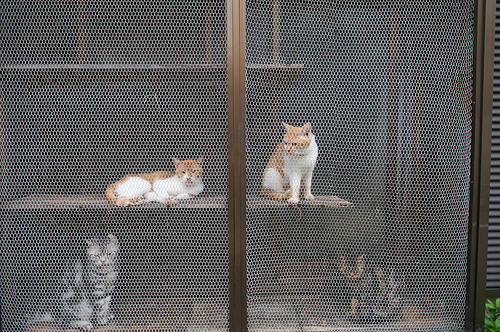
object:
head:
[282, 121, 312, 153]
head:
[338, 252, 365, 278]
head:
[172, 155, 204, 181]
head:
[84, 235, 120, 265]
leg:
[116, 188, 143, 206]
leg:
[287, 175, 302, 203]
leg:
[288, 171, 302, 197]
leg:
[98, 284, 115, 315]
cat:
[104, 156, 205, 207]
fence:
[296, 46, 465, 122]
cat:
[11, 233, 123, 331]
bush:
[482, 299, 499, 332]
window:
[0, 69, 230, 155]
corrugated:
[485, 167, 498, 289]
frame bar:
[226, 57, 248, 332]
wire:
[264, 273, 429, 303]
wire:
[412, 200, 456, 211]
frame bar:
[464, 160, 489, 331]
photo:
[0, 0, 499, 332]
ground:
[255, 324, 350, 331]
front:
[287, 198, 300, 204]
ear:
[302, 122, 312, 131]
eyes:
[292, 143, 297, 146]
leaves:
[485, 318, 495, 332]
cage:
[0, 0, 500, 331]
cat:
[260, 121, 319, 205]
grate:
[60, 116, 105, 135]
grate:
[15, 50, 103, 82]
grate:
[2, 210, 59, 262]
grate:
[373, 208, 473, 249]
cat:
[338, 254, 407, 325]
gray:
[67, 321, 88, 332]